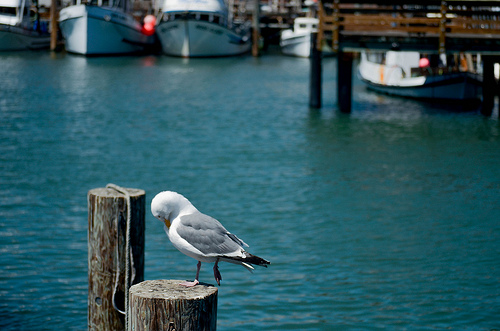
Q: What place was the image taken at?
A: It was taken at the river.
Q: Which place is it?
A: It is a river.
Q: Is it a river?
A: Yes, it is a river.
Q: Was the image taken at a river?
A: Yes, it was taken in a river.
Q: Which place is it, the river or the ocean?
A: It is the river.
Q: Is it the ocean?
A: No, it is the river.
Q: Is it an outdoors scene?
A: Yes, it is outdoors.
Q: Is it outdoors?
A: Yes, it is outdoors.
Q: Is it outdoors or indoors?
A: It is outdoors.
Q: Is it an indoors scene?
A: No, it is outdoors.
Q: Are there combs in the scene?
A: No, there are no combs.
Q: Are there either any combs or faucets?
A: No, there are no combs or faucets.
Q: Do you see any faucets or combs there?
A: No, there are no combs or faucets.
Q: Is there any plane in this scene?
A: No, there are no airplanes.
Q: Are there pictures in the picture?
A: No, there are no pictures.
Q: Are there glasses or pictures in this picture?
A: No, there are no pictures or glasses.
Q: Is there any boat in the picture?
A: Yes, there is a boat.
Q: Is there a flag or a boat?
A: Yes, there is a boat.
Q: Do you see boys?
A: No, there are no boys.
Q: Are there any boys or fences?
A: No, there are no boys or fences.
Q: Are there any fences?
A: No, there are no fences.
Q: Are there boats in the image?
A: Yes, there is a boat.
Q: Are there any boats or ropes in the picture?
A: Yes, there is a boat.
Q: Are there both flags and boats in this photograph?
A: No, there is a boat but no flags.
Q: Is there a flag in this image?
A: No, there are no flags.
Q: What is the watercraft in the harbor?
A: The watercraft is a boat.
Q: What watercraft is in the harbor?
A: The watercraft is a boat.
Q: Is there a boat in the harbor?
A: Yes, there is a boat in the harbor.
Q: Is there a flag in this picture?
A: No, there are no flags.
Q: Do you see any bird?
A: Yes, there is a bird.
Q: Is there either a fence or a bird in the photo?
A: Yes, there is a bird.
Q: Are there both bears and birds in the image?
A: No, there is a bird but no bears.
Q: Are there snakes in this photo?
A: No, there are no snakes.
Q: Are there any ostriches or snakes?
A: No, there are no snakes or ostriches.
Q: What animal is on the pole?
A: The bird is on the pole.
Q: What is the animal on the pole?
A: The animal is a bird.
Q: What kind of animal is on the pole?
A: The animal is a bird.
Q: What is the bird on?
A: The bird is on the pole.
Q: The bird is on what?
A: The bird is on the pole.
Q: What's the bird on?
A: The bird is on the pole.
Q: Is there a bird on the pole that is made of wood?
A: Yes, there is a bird on the pole.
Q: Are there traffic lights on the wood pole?
A: No, there is a bird on the pole.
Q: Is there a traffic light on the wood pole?
A: No, there is a bird on the pole.